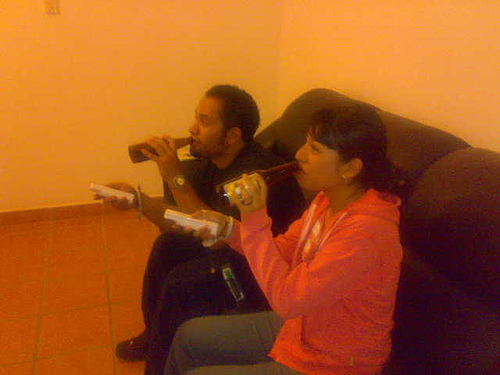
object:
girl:
[164, 104, 405, 375]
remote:
[162, 208, 221, 238]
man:
[93, 84, 308, 375]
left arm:
[167, 175, 288, 257]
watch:
[174, 175, 187, 186]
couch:
[161, 88, 500, 375]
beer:
[127, 136, 196, 164]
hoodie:
[224, 189, 406, 375]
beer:
[214, 162, 303, 210]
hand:
[93, 181, 138, 210]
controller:
[87, 180, 135, 205]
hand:
[172, 210, 233, 240]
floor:
[0, 233, 109, 374]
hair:
[309, 107, 405, 194]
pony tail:
[375, 155, 408, 194]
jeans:
[164, 312, 317, 375]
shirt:
[179, 139, 312, 238]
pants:
[141, 235, 273, 374]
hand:
[232, 173, 268, 213]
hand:
[141, 134, 184, 182]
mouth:
[190, 136, 201, 145]